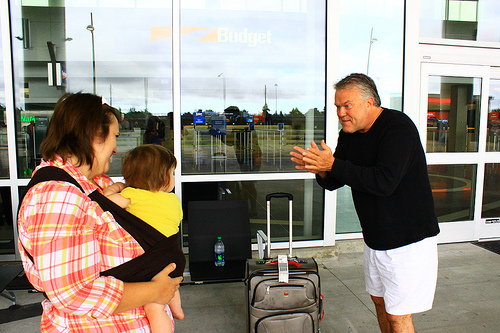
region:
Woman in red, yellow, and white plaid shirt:
[16, 90, 217, 332]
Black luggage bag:
[179, 179, 263, 279]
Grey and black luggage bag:
[235, 187, 341, 328]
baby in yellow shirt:
[101, 140, 208, 330]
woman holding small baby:
[15, 96, 186, 328]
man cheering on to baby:
[273, 80, 449, 330]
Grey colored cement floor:
[2, 240, 497, 331]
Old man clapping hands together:
[285, 75, 466, 331]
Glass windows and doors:
[2, 0, 493, 242]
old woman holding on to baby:
[16, 91, 192, 329]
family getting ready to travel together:
[20, 8, 447, 330]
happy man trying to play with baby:
[290, 68, 442, 329]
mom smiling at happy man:
[16, 83, 129, 331]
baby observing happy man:
[117, 140, 186, 327]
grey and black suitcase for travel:
[243, 189, 323, 331]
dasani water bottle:
[212, 233, 229, 268]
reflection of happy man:
[202, 103, 259, 229]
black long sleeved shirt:
[314, 110, 442, 251]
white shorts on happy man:
[359, 234, 442, 312]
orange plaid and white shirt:
[17, 164, 149, 331]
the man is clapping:
[263, 67, 472, 262]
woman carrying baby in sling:
[17, 88, 268, 330]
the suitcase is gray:
[240, 249, 326, 329]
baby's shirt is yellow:
[109, 185, 201, 242]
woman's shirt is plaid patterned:
[10, 149, 187, 326]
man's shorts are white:
[351, 222, 466, 307]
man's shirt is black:
[326, 122, 458, 258]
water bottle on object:
[203, 215, 242, 273]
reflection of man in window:
[217, 99, 283, 196]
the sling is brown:
[10, 171, 187, 277]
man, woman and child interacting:
[16, 66, 439, 327]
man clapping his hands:
[287, 70, 437, 330]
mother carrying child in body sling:
[12, 85, 182, 320]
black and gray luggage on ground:
[182, 176, 323, 327]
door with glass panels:
[420, 60, 496, 240]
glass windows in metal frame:
[1, 0, 331, 260]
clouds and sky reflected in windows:
[57, 7, 327, 117]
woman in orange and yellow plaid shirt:
[15, 81, 175, 326]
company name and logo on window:
[140, 11, 272, 48]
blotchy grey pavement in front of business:
[180, 237, 496, 327]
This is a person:
[281, 62, 446, 328]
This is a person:
[15, 80, 125, 330]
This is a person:
[110, 110, 210, 326]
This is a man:
[285, 50, 445, 326]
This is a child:
[120, 126, 205, 331]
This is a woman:
[38, 88, 127, 331]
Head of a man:
[332, 43, 395, 136]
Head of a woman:
[45, 68, 118, 193]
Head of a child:
[118, 123, 200, 209]